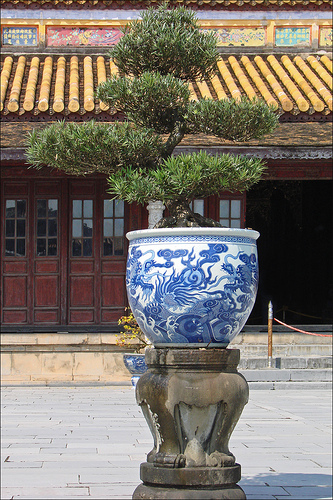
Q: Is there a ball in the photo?
A: No, there are no balls.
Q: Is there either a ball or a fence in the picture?
A: No, there are no balls or fences.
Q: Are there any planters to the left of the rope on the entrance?
A: Yes, there is a planter to the left of the rope.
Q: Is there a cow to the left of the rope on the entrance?
A: No, there is a planter to the left of the rope.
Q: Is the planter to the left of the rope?
A: Yes, the planter is to the left of the rope.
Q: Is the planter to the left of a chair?
A: No, the planter is to the left of the rope.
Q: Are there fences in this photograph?
A: No, there are no fences.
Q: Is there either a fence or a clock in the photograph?
A: No, there are no fences or clocks.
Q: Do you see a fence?
A: No, there are no fences.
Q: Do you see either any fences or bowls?
A: No, there are no fences or bowls.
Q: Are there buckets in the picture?
A: No, there are no buckets.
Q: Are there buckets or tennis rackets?
A: No, there are no buckets or tennis rackets.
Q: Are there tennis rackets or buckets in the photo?
A: No, there are no buckets or tennis rackets.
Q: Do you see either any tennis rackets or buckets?
A: No, there are no buckets or tennis rackets.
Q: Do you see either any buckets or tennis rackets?
A: No, there are no buckets or tennis rackets.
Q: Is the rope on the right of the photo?
A: Yes, the rope is on the right of the image.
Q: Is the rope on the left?
A: No, the rope is on the right of the image.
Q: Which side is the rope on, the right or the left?
A: The rope is on the right of the image.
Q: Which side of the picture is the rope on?
A: The rope is on the right of the image.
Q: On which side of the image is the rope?
A: The rope is on the right of the image.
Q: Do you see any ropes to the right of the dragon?
A: Yes, there is a rope to the right of the dragon.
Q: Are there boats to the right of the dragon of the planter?
A: No, there is a rope to the right of the dragon.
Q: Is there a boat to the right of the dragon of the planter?
A: No, there is a rope to the right of the dragon.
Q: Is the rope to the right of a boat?
A: No, the rope is to the right of the dragon.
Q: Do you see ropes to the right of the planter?
A: Yes, there is a rope to the right of the planter.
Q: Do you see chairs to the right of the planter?
A: No, there is a rope to the right of the planter.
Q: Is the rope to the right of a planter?
A: Yes, the rope is to the right of a planter.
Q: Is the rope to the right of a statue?
A: No, the rope is to the right of a planter.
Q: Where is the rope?
A: The rope is on the entrance.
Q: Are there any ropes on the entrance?
A: Yes, there is a rope on the entrance.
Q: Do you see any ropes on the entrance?
A: Yes, there is a rope on the entrance.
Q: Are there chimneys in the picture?
A: No, there are no chimneys.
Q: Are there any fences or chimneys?
A: No, there are no chimneys or fences.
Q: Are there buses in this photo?
A: No, there are no buses.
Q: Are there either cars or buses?
A: No, there are no buses or cars.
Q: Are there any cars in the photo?
A: No, there are no cars.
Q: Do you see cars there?
A: No, there are no cars.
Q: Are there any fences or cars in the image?
A: No, there are no cars or fences.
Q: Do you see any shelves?
A: No, there are no shelves.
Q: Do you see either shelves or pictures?
A: No, there are no shelves or pictures.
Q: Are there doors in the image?
A: Yes, there is a door.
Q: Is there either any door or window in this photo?
A: Yes, there is a door.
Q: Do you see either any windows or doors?
A: Yes, there is a door.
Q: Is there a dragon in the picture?
A: Yes, there is a dragon.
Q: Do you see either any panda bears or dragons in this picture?
A: Yes, there is a dragon.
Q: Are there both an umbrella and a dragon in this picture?
A: No, there is a dragon but no umbrellas.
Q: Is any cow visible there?
A: No, there are no cows.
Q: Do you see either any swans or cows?
A: No, there are no cows or swans.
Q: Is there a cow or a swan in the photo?
A: No, there are no cows or swans.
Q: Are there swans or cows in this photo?
A: No, there are no cows or swans.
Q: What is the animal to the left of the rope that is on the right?
A: The animal is a dragon.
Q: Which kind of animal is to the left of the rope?
A: The animal is a dragon.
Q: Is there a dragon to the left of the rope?
A: Yes, there is a dragon to the left of the rope.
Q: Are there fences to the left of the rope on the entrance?
A: No, there is a dragon to the left of the rope.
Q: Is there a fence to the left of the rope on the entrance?
A: No, there is a dragon to the left of the rope.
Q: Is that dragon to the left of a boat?
A: No, the dragon is to the left of the rope.